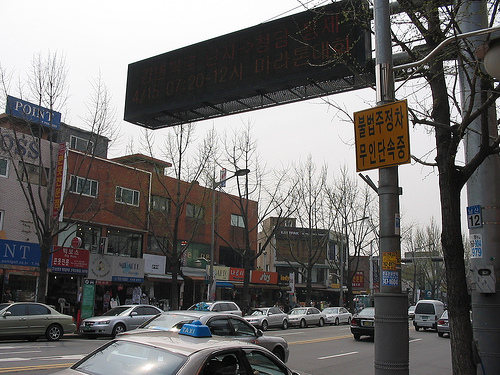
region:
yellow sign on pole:
[345, 113, 411, 162]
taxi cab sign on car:
[162, 312, 211, 339]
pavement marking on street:
[314, 345, 349, 364]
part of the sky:
[52, 10, 152, 47]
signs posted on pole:
[371, 248, 411, 296]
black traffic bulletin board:
[123, 22, 376, 97]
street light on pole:
[208, 166, 255, 191]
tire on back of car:
[41, 324, 68, 343]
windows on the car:
[16, 307, 45, 317]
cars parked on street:
[263, 307, 340, 325]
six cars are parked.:
[5, 280, 355, 333]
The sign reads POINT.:
[7, 91, 64, 130]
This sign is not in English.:
[351, 102, 413, 176]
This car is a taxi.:
[85, 327, 300, 373]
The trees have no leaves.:
[12, 57, 415, 294]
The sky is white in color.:
[11, 45, 343, 195]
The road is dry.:
[299, 337, 356, 367]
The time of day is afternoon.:
[23, 57, 433, 333]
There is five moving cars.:
[50, 267, 477, 373]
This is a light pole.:
[206, 162, 238, 304]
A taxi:
[126, 318, 273, 373]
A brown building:
[56, 143, 257, 251]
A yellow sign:
[343, 91, 424, 191]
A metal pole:
[365, 191, 427, 317]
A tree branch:
[423, 62, 493, 272]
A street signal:
[130, 23, 338, 96]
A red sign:
[53, 246, 93, 273]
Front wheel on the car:
[260, 318, 272, 329]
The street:
[306, 331, 353, 370]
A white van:
[408, 296, 436, 327]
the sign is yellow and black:
[347, 98, 422, 178]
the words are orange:
[153, 51, 318, 79]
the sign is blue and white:
[171, 316, 214, 341]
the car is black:
[345, 300, 387, 345]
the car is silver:
[79, 300, 182, 344]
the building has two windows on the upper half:
[63, 144, 149, 237]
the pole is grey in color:
[367, 55, 399, 351]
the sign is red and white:
[251, 265, 281, 287]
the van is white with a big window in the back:
[409, 288, 442, 329]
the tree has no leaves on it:
[280, 162, 344, 302]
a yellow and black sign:
[345, 95, 416, 172]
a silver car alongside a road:
[77, 299, 168, 334]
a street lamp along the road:
[207, 161, 252, 312]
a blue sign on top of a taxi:
[176, 318, 213, 337]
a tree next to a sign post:
[394, 1, 498, 372]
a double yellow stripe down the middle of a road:
[282, 326, 351, 350]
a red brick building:
[148, 172, 260, 282]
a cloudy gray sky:
[4, 1, 498, 255]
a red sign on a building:
[46, 241, 97, 271]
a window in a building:
[112, 183, 143, 207]